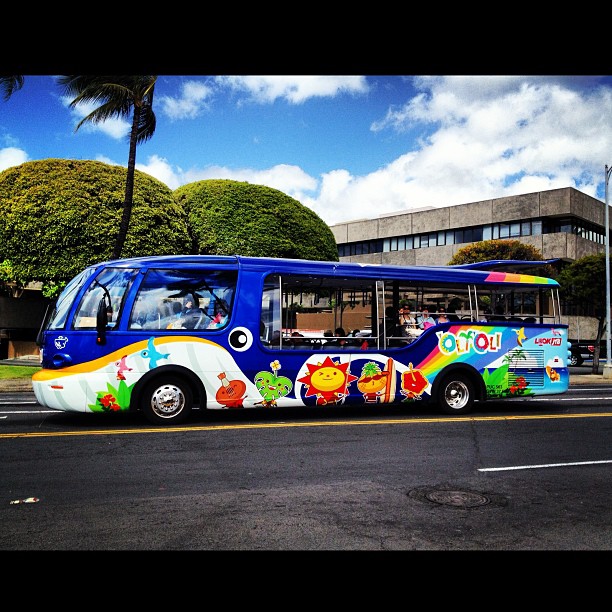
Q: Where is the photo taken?
A: On a roadway.